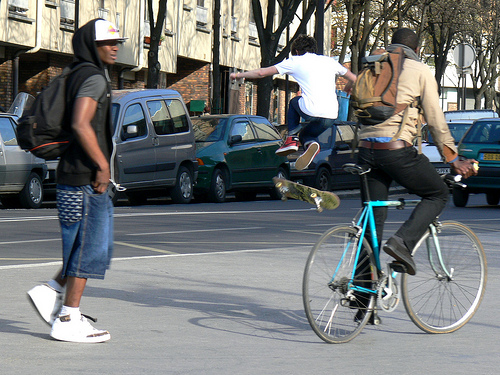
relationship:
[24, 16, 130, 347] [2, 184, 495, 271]
man on road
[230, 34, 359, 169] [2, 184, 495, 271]
man on road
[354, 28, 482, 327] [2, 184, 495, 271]
man on road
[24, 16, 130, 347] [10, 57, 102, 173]
man carrying backpack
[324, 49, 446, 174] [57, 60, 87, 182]
backpack on back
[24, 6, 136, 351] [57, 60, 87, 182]
man has back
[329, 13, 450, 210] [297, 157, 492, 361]
man riding bike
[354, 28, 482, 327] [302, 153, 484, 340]
man riding bike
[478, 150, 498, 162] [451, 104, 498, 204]
plate on car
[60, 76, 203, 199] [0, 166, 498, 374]
car on side of road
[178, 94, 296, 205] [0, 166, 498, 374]
car on side of road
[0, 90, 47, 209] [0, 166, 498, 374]
car on side of road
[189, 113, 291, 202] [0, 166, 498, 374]
car on side of road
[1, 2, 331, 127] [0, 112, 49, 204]
building near car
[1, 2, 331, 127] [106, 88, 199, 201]
building near car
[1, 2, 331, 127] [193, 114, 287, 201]
building near car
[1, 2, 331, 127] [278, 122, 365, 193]
building near car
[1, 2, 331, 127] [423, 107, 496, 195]
building near car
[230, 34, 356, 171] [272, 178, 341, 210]
man on skateboard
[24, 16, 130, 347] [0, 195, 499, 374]
man on road